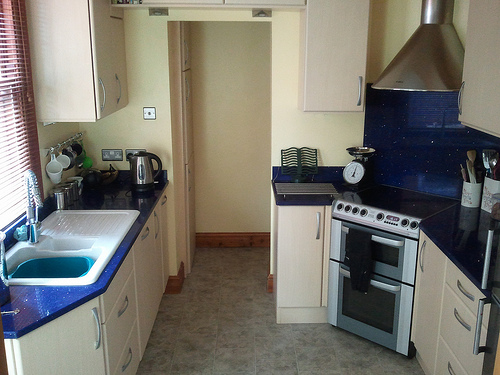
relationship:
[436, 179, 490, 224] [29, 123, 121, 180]
mugs on rod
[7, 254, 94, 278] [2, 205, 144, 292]
plastic bin on sink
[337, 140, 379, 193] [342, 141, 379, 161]
scale has dial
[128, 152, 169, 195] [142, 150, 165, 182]
pot has handle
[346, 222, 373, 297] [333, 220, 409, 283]
towel hanging from oven door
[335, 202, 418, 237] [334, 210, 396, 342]
dials for oven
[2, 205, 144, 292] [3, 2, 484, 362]
sink in kitchen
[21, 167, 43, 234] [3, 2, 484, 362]
faucet in kitchen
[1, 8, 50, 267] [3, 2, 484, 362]
window in kitchen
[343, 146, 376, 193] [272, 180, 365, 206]
scale on table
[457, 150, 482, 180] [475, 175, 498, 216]
utensils in container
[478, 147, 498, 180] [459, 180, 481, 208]
utensils in container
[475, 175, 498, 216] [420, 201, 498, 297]
container on counter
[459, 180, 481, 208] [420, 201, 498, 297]
container on counter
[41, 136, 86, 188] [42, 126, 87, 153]
cups hanging on rack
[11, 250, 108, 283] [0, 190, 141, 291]
bucket in sink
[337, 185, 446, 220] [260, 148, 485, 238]
stove in corner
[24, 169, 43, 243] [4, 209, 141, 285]
faucett over sink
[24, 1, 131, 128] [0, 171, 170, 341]
cabinets over counter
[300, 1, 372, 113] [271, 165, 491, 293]
cabinets over counter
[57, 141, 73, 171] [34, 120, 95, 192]
cup hangs from wall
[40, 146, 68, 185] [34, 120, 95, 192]
cup hangs from wall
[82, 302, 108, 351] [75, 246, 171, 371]
handle on cabinet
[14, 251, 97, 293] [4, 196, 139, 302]
tub in sink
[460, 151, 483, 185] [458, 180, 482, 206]
utensils in canister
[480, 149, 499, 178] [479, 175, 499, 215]
utensils in canister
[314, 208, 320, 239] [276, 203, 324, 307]
handle on cabinet